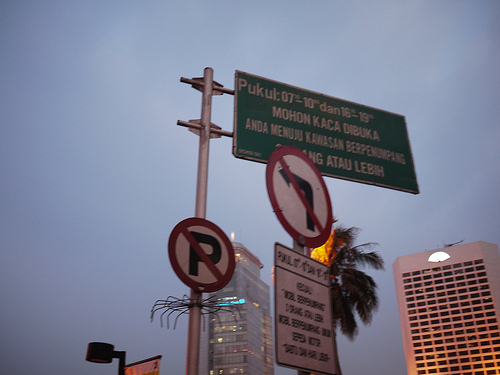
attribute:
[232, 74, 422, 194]
sign — green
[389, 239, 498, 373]
building — tall, white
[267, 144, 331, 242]
sign — round, red, white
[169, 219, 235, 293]
sign — red, white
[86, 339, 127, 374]
streetlight — black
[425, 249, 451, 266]
logo — lighted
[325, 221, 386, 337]
palm tree — green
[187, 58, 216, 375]
pole — metal, silver, thin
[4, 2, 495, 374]
sky — cloudless, clear, grey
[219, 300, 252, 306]
light — blue